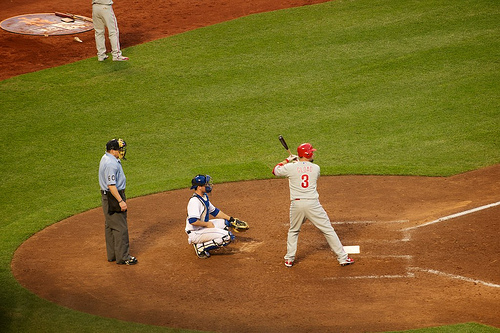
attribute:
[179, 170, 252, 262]
catcher — kneeling, squatting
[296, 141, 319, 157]
helmet — red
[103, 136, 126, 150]
cap — black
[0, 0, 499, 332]
field — chalked, grassy, dirty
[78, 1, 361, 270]
people — playing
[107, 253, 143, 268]
cleats — black, white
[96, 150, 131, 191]
shirt — blue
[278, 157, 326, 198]
jersey — gray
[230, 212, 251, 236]
glove — black, yellow, brown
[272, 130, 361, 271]
batter — standing, ready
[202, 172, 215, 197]
facemask — blue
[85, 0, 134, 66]
person — standing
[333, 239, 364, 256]
base — white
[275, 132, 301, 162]
bat — wooden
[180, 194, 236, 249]
uniform — white